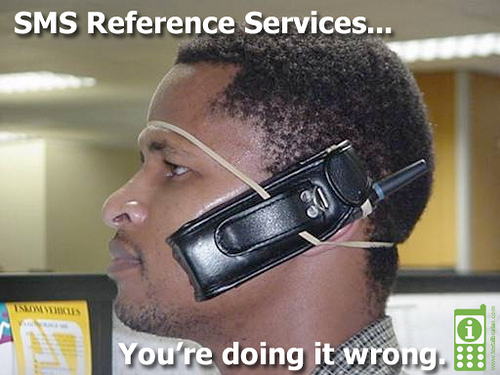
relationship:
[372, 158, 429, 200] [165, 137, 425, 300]
antenna on phone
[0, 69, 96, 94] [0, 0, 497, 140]
light on ceiling